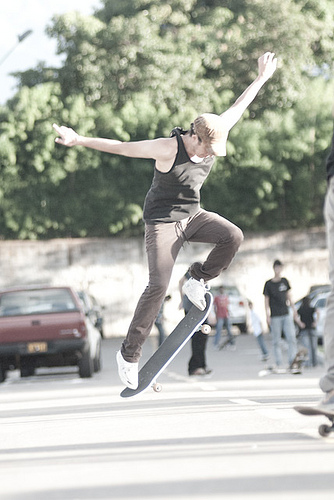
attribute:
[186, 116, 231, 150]
hat — brown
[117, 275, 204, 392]
shoes — white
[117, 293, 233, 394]
board — black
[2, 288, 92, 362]
car — red, parked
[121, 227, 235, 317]
pants — brown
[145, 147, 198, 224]
shirt — black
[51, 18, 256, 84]
trees — green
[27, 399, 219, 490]
road — grey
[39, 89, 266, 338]
boy — skating, white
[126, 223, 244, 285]
jeans — brown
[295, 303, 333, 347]
woman — standing